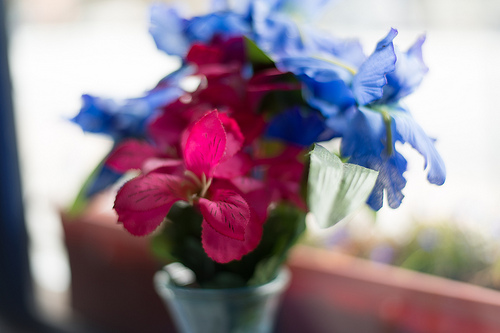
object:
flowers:
[58, 3, 450, 274]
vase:
[149, 263, 297, 331]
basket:
[61, 184, 497, 332]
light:
[21, 9, 496, 246]